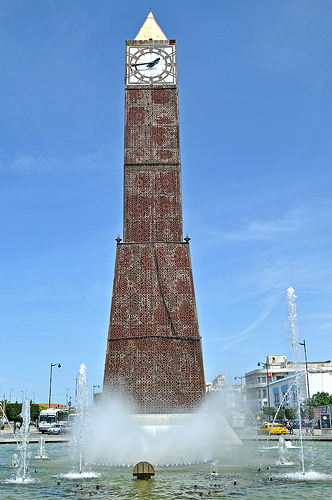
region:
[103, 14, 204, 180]
this is part of a huge clock tower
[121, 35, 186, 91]
the clock reads 1:45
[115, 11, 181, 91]
the top of the clock tower has a point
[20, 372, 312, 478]
water fountains at the base of the tower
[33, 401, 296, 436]
traffic near the tower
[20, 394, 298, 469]
the clock tower is located in a body of water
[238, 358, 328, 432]
buildings in the background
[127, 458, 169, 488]
some kind of object on the water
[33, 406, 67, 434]
a bus near the tower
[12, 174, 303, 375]
it is a clear and sunny day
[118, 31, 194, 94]
A clock on top of structure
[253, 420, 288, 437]
a yellow taxi cab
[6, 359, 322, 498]
water spraying up from fountains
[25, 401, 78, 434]
a white and black bus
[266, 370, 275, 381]
a red sign on a pole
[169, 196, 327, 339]
white wispy clouds in the sky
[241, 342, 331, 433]
two white buildings side by side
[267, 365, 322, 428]
a white building with blue trim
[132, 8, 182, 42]
a white triangle above clock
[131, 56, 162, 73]
black hands of the clock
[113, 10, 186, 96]
Clock on top of tower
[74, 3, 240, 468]
Clock on tower in fountain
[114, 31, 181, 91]
It is almost 1:45 on clock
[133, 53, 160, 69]
Hands on the clock are black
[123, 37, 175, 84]
Face of the clock is white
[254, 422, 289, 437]
Yellow cab in the distance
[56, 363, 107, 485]
Water in fountain is high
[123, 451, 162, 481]
Light in fountain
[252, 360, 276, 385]
Traffic signal in the distance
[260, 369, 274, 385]
Traffic signal is lit red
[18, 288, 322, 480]
water spraying up from pool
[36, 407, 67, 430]
bus going down street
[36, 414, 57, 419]
front window of bus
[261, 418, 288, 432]
yellow car driving down street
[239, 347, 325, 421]
white buildings in background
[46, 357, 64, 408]
black street light in background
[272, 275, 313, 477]
tallest spray of water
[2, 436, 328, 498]
pool of water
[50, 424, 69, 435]
white car driving down road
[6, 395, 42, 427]
trees along sidewalk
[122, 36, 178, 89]
A square clock face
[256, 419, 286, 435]
A yellow taxi cab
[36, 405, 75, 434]
A blue and white bus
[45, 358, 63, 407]
A lamp post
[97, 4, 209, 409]
A tall clock tower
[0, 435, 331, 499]
A pond of water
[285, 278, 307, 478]
A et of water going into the air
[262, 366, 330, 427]
A white and blue building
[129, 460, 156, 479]
A small light in the water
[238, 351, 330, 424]
A three story building